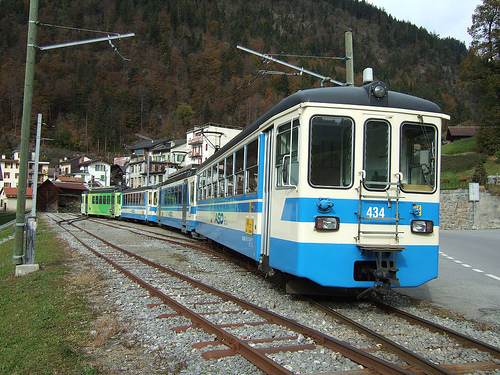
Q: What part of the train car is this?
A: The front windshield.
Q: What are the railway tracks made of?
A: Steel.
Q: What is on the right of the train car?
A: Electric power poles.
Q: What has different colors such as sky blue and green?
A: The train's compartments.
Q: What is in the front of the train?
A: Windows.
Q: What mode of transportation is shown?
A: Train.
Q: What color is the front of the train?
A: Blue and white.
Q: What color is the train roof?
A: Black.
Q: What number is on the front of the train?
A: 434.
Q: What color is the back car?
A: Yellow and green.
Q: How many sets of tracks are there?
A: Two.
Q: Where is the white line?
A: Road.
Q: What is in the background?
A: Hills.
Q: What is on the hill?
A: Trees.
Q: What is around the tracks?
A: Gravel.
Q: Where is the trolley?
A: On the tracks.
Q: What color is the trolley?
A: Blue, green, and white.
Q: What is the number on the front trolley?
A: 434.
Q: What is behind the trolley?
A: Houses.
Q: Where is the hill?
A: Behind the trolley.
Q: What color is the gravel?
A: Gray.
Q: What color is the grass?
A: Green.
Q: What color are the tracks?
A: Brown.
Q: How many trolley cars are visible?
A: 4.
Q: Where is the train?
A: On the track.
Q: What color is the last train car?
A: Green.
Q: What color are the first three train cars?
A: Blue and white.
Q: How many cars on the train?
A: Four.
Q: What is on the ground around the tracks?
A: Stones.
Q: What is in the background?
A: Trees, houses.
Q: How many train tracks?
A: Two.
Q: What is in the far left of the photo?
A: Grass.